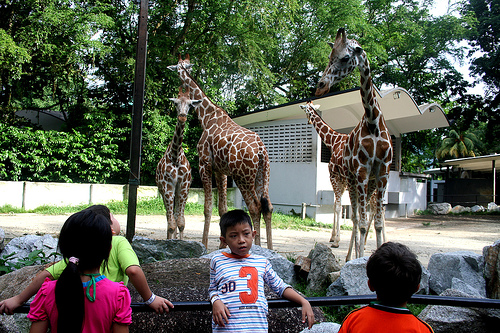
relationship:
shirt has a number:
[210, 250, 293, 333] [238, 265, 260, 304]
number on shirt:
[238, 265, 260, 304] [210, 250, 293, 333]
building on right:
[232, 86, 451, 221] [221, 1, 499, 332]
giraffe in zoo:
[168, 55, 275, 254] [1, 0, 499, 330]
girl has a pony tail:
[27, 212, 132, 332] [54, 256, 85, 332]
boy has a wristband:
[207, 209, 313, 332] [211, 295, 221, 304]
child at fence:
[207, 209, 313, 332] [3, 291, 499, 332]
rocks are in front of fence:
[6, 230, 499, 332] [1, 179, 237, 214]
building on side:
[232, 86, 451, 221] [221, 1, 499, 332]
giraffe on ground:
[168, 55, 275, 254] [10, 204, 499, 260]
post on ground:
[300, 202, 309, 221] [10, 204, 499, 260]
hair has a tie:
[55, 208, 115, 332] [68, 256, 80, 265]